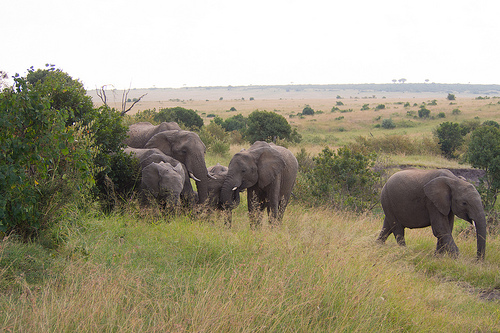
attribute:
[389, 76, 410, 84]
trees — green, tall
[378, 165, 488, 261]
elephant — walking, baby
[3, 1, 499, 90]
sky — white, clear, hazy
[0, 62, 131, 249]
bushes — large, green, wild, growing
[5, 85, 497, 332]
ground — green, beige, brown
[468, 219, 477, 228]
tusk — white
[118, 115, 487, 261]
elephants — grey, small, walking, grazing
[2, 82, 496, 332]
grass — tall, brown, light green, green, dry, dying, patchy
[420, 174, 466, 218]
ears — big